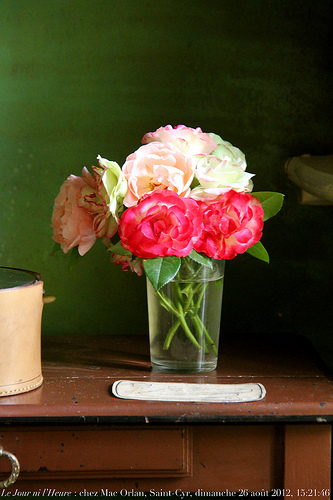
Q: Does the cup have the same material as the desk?
A: No, the cup is made of glass and the desk is made of wood.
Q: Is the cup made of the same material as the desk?
A: No, the cup is made of glass and the desk is made of wood.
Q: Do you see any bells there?
A: No, there are no bells.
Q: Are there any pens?
A: No, there are no pens.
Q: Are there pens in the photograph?
A: No, there are no pens.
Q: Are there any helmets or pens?
A: No, there are no pens or helmets.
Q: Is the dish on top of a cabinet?
A: No, the dish is on top of the desk.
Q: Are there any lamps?
A: No, there are no lamps.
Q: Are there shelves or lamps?
A: No, there are no lamps or shelves.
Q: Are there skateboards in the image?
A: No, there are no skateboards.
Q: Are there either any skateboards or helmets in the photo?
A: No, there are no skateboards or helmets.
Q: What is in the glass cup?
A: The flower is in the cup.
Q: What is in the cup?
A: The flower is in the cup.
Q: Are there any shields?
A: No, there are no shields.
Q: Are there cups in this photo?
A: Yes, there is a cup.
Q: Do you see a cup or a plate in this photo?
A: Yes, there is a cup.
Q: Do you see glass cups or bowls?
A: Yes, there is a glass cup.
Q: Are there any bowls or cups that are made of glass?
A: Yes, the cup is made of glass.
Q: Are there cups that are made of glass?
A: Yes, there is a cup that is made of glass.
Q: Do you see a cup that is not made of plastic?
A: Yes, there is a cup that is made of glass.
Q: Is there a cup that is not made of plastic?
A: Yes, there is a cup that is made of glass.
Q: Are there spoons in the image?
A: No, there are no spoons.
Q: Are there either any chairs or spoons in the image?
A: No, there are no spoons or chairs.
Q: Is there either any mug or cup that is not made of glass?
A: No, there is a cup but it is made of glass.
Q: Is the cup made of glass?
A: Yes, the cup is made of glass.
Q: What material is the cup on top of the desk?
A: The cup is made of glass.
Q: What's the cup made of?
A: The cup is made of glass.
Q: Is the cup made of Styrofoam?
A: No, the cup is made of glass.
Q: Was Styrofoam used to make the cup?
A: No, the cup is made of glass.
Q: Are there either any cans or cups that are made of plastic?
A: No, there is a cup but it is made of glass.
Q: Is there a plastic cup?
A: No, there is a cup but it is made of glass.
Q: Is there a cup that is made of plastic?
A: No, there is a cup but it is made of glass.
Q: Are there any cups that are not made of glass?
A: No, there is a cup but it is made of glass.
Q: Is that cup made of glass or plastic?
A: The cup is made of glass.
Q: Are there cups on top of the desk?
A: Yes, there is a cup on top of the desk.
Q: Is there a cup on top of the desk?
A: Yes, there is a cup on top of the desk.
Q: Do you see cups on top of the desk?
A: Yes, there is a cup on top of the desk.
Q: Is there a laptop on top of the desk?
A: No, there is a cup on top of the desk.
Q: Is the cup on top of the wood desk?
A: Yes, the cup is on top of the desk.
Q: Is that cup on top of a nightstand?
A: No, the cup is on top of the desk.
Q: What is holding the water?
A: The cup is holding the water.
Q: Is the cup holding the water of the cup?
A: Yes, the cup is holding the water.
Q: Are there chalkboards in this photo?
A: No, there are no chalkboards.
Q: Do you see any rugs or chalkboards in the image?
A: No, there are no chalkboards or rugs.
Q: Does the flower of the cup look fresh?
A: Yes, the flower is fresh.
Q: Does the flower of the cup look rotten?
A: No, the flower is fresh.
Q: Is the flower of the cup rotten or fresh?
A: The flower is fresh.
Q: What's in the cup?
A: The flower is in the cup.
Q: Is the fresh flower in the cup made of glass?
A: Yes, the flower is in the cup.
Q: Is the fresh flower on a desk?
A: Yes, the flower is on a desk.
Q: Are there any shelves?
A: No, there are no shelves.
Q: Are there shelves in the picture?
A: No, there are no shelves.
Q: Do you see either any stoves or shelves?
A: No, there are no shelves or stoves.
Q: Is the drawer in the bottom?
A: Yes, the drawer is in the bottom of the image.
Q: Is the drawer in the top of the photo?
A: No, the drawer is in the bottom of the image.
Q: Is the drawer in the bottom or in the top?
A: The drawer is in the bottom of the image.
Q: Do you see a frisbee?
A: No, there are no frisbees.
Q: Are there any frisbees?
A: No, there are no frisbees.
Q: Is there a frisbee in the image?
A: No, there are no frisbees.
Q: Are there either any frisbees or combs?
A: No, there are no frisbees or combs.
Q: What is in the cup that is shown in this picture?
A: The flower is in the cup.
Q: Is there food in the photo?
A: No, there is no food.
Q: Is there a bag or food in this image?
A: No, there are no food or bags.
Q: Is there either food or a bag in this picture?
A: No, there are no food or bags.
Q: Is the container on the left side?
A: Yes, the container is on the left of the image.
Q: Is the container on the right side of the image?
A: No, the container is on the left of the image.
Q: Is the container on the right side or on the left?
A: The container is on the left of the image.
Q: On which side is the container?
A: The container is on the left of the image.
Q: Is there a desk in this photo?
A: Yes, there is a desk.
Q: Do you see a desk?
A: Yes, there is a desk.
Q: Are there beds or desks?
A: Yes, there is a desk.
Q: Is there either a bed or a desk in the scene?
A: Yes, there is a desk.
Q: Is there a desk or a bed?
A: Yes, there is a desk.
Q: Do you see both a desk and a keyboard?
A: No, there is a desk but no keyboards.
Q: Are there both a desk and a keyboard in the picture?
A: No, there is a desk but no keyboards.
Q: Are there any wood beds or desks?
A: Yes, there is a wood desk.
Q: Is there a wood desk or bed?
A: Yes, there is a wood desk.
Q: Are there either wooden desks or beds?
A: Yes, there is a wood desk.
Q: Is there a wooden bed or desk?
A: Yes, there is a wood desk.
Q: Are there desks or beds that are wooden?
A: Yes, the desk is wooden.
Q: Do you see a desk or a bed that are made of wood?
A: Yes, the desk is made of wood.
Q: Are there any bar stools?
A: No, there are no bar stools.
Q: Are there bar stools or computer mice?
A: No, there are no bar stools or computer mice.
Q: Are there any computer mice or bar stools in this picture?
A: No, there are no bar stools or computer mice.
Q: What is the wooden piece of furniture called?
A: The piece of furniture is a desk.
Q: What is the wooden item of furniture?
A: The piece of furniture is a desk.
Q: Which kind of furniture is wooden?
A: The furniture is a desk.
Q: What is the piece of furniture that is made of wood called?
A: The piece of furniture is a desk.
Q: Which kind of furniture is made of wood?
A: The furniture is a desk.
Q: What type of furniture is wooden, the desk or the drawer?
A: The desk is wooden.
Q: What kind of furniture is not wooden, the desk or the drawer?
A: The drawer is not wooden.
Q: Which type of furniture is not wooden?
A: The furniture is a drawer.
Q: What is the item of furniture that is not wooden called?
A: The piece of furniture is a drawer.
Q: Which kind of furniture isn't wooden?
A: The furniture is a drawer.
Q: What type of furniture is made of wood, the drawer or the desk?
A: The desk is made of wood.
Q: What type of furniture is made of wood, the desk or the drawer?
A: The desk is made of wood.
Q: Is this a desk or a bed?
A: This is a desk.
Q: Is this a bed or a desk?
A: This is a desk.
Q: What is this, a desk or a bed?
A: This is a desk.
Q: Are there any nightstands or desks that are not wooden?
A: No, there is a desk but it is wooden.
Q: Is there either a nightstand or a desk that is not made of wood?
A: No, there is a desk but it is made of wood.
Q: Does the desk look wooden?
A: Yes, the desk is wooden.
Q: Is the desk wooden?
A: Yes, the desk is wooden.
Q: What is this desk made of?
A: The desk is made of wood.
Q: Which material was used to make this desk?
A: The desk is made of wood.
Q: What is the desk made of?
A: The desk is made of wood.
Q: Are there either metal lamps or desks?
A: No, there is a desk but it is wooden.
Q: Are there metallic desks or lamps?
A: No, there is a desk but it is wooden.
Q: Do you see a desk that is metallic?
A: No, there is a desk but it is wooden.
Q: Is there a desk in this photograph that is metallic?
A: No, there is a desk but it is wooden.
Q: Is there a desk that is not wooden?
A: No, there is a desk but it is wooden.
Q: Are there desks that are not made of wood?
A: No, there is a desk but it is made of wood.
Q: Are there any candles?
A: No, there are no candles.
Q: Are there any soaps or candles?
A: No, there are no candles or soaps.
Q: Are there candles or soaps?
A: No, there are no candles or soaps.